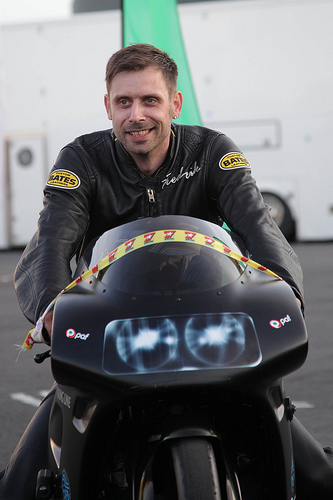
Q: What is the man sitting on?
A: A motorcycle.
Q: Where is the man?
A: On the motorcycle.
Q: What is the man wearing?
A: A black jacket.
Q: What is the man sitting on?
A: The motorcycle.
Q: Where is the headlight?
A: On the motorcycle.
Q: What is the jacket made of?
A: Leather.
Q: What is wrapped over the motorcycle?
A: A yellow ribbon.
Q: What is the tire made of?
A: Rubber.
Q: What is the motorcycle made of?
A: Metal.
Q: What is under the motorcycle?
A: Asphalt.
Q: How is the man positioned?
A: He is sitting.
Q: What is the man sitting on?
A: A motorcycle.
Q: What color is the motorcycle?
A: Black.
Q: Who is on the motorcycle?
A: A man.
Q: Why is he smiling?
A: He is happy.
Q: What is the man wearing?
A: A jacket.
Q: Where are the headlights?
A: On the front of the motorcycle.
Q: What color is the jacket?
A: Black.